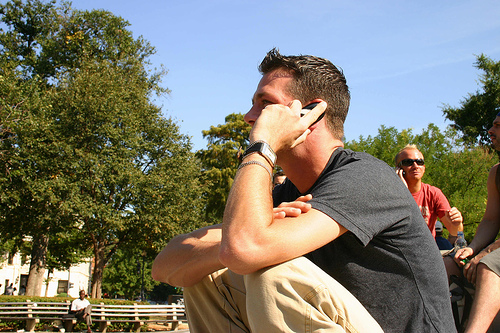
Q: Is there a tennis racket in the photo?
A: No, there are no rackets.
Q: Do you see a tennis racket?
A: No, there are no rackets.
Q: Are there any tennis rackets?
A: No, there are no tennis rackets.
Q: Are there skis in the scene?
A: No, there are no skis.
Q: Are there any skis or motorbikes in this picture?
A: No, there are no skis or motorbikes.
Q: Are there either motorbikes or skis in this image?
A: No, there are no skis or motorbikes.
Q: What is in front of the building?
A: The tree is in front of the building.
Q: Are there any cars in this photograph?
A: No, there are no cars.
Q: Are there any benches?
A: Yes, there is a bench.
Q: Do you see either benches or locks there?
A: Yes, there is a bench.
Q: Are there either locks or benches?
A: Yes, there is a bench.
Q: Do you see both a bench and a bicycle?
A: No, there is a bench but no bicycles.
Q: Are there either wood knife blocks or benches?
A: Yes, there is a wood bench.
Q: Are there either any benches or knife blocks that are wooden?
A: Yes, the bench is wooden.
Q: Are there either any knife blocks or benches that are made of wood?
A: Yes, the bench is made of wood.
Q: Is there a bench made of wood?
A: Yes, there is a bench that is made of wood.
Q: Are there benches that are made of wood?
A: Yes, there is a bench that is made of wood.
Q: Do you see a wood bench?
A: Yes, there is a bench that is made of wood.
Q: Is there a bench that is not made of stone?
A: Yes, there is a bench that is made of wood.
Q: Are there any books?
A: No, there are no books.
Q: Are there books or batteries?
A: No, there are no books or batteries.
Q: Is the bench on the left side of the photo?
A: Yes, the bench is on the left of the image.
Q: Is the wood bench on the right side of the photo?
A: No, the bench is on the left of the image.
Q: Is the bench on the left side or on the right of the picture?
A: The bench is on the left of the image.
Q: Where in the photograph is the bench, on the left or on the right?
A: The bench is on the left of the image.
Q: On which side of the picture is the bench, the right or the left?
A: The bench is on the left of the image.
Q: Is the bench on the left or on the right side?
A: The bench is on the left of the image.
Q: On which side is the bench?
A: The bench is on the left of the image.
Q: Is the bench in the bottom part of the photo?
A: Yes, the bench is in the bottom of the image.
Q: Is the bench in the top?
A: No, the bench is in the bottom of the image.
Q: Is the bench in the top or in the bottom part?
A: The bench is in the bottom of the image.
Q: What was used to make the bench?
A: The bench is made of wood.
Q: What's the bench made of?
A: The bench is made of wood.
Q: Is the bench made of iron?
A: No, the bench is made of wood.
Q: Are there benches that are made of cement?
A: No, there is a bench but it is made of wood.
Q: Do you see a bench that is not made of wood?
A: No, there is a bench but it is made of wood.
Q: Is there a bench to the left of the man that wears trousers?
A: Yes, there is a bench to the left of the man.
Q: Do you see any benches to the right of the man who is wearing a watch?
A: No, the bench is to the left of the man.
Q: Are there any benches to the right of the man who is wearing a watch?
A: No, the bench is to the left of the man.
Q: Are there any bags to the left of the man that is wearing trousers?
A: No, there is a bench to the left of the man.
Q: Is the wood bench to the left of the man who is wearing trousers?
A: Yes, the bench is to the left of the man.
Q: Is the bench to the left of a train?
A: No, the bench is to the left of the man.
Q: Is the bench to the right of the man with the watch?
A: No, the bench is to the left of the man.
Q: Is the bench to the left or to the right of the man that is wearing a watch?
A: The bench is to the left of the man.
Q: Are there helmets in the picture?
A: No, there are no helmets.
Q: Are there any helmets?
A: No, there are no helmets.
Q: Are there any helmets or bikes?
A: No, there are no helmets or bikes.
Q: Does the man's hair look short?
A: Yes, the hair is short.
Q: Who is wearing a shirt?
A: The man is wearing a shirt.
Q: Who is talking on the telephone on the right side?
A: The man is talking on the phone.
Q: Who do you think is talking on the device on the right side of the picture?
A: The man is talking on the phone.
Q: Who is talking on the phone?
A: The man is talking on the phone.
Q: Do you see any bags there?
A: No, there are no bags.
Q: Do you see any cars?
A: No, there are no cars.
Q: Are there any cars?
A: No, there are no cars.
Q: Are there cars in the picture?
A: No, there are no cars.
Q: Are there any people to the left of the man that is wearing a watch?
A: Yes, there is a person to the left of the man.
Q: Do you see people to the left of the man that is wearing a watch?
A: Yes, there is a person to the left of the man.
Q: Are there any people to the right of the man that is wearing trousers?
A: No, the person is to the left of the man.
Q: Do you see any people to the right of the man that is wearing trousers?
A: No, the person is to the left of the man.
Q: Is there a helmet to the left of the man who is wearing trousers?
A: No, there is a person to the left of the man.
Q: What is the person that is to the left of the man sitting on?
A: The person is sitting on the bench.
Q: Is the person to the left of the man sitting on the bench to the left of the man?
A: Yes, the person is sitting on the bench.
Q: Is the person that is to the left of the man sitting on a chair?
A: No, the person is sitting on the bench.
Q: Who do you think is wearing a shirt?
A: The man is wearing a shirt.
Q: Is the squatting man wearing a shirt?
A: Yes, the man is wearing a shirt.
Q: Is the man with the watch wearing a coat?
A: No, the man is wearing a shirt.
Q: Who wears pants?
A: The man wears pants.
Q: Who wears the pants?
A: The man wears pants.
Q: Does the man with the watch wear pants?
A: Yes, the man wears pants.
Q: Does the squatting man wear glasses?
A: No, the man wears pants.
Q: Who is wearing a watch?
A: The man is wearing a watch.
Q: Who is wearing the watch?
A: The man is wearing a watch.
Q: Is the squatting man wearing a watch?
A: Yes, the man is wearing a watch.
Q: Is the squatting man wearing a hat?
A: No, the man is wearing a watch.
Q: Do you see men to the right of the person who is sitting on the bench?
A: Yes, there is a man to the right of the person.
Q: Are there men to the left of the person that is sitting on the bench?
A: No, the man is to the right of the person.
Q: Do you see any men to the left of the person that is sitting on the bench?
A: No, the man is to the right of the person.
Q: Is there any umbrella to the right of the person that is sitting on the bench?
A: No, there is a man to the right of the person.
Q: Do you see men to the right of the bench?
A: Yes, there is a man to the right of the bench.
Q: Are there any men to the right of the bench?
A: Yes, there is a man to the right of the bench.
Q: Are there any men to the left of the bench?
A: No, the man is to the right of the bench.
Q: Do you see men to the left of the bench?
A: No, the man is to the right of the bench.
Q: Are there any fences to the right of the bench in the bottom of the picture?
A: No, there is a man to the right of the bench.